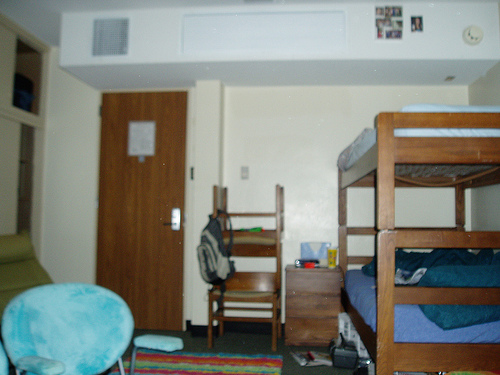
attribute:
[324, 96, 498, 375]
bunkbed — wooden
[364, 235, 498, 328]
bedding — blue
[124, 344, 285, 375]
rug — striped, green, red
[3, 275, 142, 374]
chair — fuzzy, round, circular, shiny blue, turquoise, folding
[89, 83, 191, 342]
door — wooden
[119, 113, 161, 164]
sign — white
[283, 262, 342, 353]
night table — brown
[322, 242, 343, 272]
item — yellow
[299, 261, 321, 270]
item — red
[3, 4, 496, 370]
room — brown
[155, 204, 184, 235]
door knob — silver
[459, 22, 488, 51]
fire alarm — white, smoke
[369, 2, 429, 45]
pictures — personal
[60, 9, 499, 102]
wall — clear white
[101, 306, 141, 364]
arm rest — blue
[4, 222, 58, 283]
chair — green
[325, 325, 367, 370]
box — black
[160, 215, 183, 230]
opener — silver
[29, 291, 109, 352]
material — blue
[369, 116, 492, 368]
frame — wooden